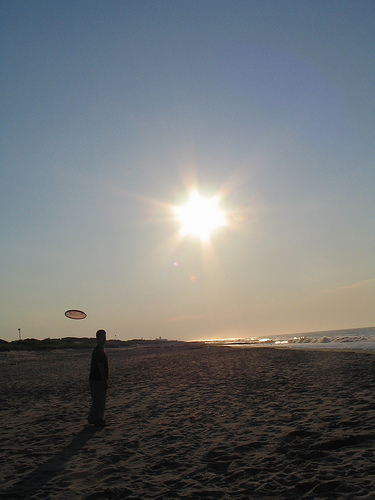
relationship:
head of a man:
[93, 327, 108, 344] [83, 327, 114, 427]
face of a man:
[98, 330, 106, 343] [84, 327, 118, 425]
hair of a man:
[95, 330, 105, 342] [83, 327, 114, 427]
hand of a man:
[99, 378, 110, 386] [85, 325, 112, 425]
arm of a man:
[93, 351, 107, 383] [91, 327, 114, 426]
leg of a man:
[91, 377, 106, 426] [83, 327, 114, 427]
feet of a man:
[88, 417, 109, 427] [85, 323, 108, 429]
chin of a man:
[102, 339, 107, 343] [85, 327, 110, 429]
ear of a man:
[95, 334, 101, 342] [83, 325, 111, 428]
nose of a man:
[103, 336, 107, 344] [84, 327, 112, 434]